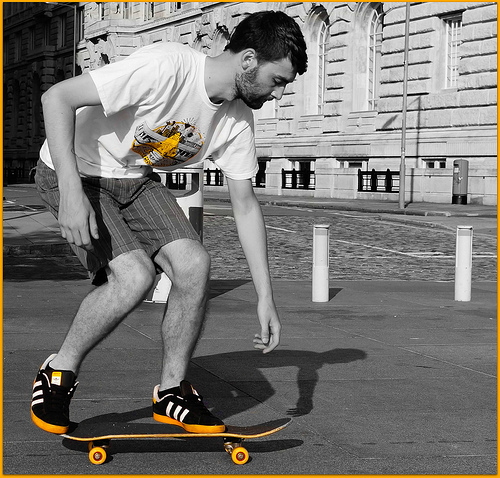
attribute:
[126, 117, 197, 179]
logo — yellow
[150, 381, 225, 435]
sneaker — black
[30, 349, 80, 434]
sneaker — black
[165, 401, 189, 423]
stripes — white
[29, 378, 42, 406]
stripes — white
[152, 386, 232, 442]
shoes — white, striped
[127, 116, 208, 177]
logo — yellow, gray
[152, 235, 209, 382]
leg — hairy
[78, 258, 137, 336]
leg — hairy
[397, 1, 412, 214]
pole — light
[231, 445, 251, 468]
wheel — orange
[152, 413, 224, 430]
trim — orange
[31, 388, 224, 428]
sneakers — black, yellow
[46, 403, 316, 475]
skateboard — his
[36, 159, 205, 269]
shorts — striped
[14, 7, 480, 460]
day — his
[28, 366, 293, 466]
accent — orange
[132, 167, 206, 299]
recepticle — trash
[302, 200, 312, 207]
traffic — through